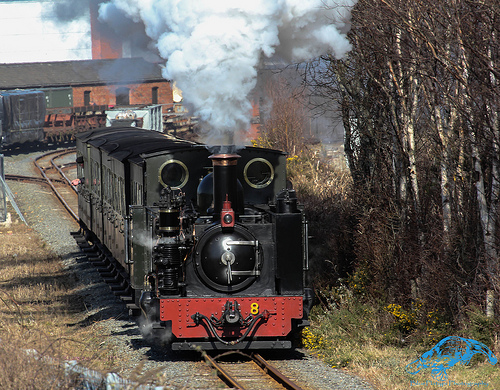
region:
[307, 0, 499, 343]
A small wooded area of dead trees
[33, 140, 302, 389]
A trains railroad tracks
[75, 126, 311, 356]
A train on the tracks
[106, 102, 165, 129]
A white train car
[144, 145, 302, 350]
The front of a train engine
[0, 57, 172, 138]
A large brick building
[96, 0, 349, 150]
Large section of smoke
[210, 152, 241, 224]
A trains engine smoke stack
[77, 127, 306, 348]
A black train on the tracks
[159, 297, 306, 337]
Red bumper section of a trains engine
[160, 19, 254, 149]
Smoke stack in the air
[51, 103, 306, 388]
Red and black train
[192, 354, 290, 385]
Dark metal train tracks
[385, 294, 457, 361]
Small yellow flowers in grass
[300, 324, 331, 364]
Small yellow flowers in grass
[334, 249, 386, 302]
Small yellow flowers in grass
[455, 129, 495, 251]
Small brown branches from tree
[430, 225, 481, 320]
Small brown branches from tree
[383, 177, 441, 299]
Small brown branches from tree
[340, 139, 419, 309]
Small brown branches from tree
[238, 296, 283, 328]
yellow number eight on front of train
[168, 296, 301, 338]
red portion on front of train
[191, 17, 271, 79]
grey smoke coming out of top of train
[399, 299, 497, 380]
blue object on the front right of photo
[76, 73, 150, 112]
red brick building in the distance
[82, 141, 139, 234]
black cars on the back of the train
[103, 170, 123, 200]
windows on side of train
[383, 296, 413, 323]
yellow small flowers on side of road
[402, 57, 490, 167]
bare trees on right of photo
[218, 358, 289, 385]
tracks in front of train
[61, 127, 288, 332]
this is a train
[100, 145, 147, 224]
the train is black in color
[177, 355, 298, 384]
this is a railway line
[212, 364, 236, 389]
this is a metal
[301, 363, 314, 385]
this is the rocks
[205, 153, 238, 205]
this is the chimney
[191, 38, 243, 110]
these are the fumes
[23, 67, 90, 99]
this is a building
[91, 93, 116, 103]
this is the wall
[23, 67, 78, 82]
this is the roof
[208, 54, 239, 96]
part of a smoke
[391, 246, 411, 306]
aprt of a lant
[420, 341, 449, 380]
part of a graphic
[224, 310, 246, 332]
aprt of a metal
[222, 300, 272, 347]
part of a metal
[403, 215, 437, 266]
part of a tree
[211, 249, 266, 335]
part of a train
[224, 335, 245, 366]
aprt of a train